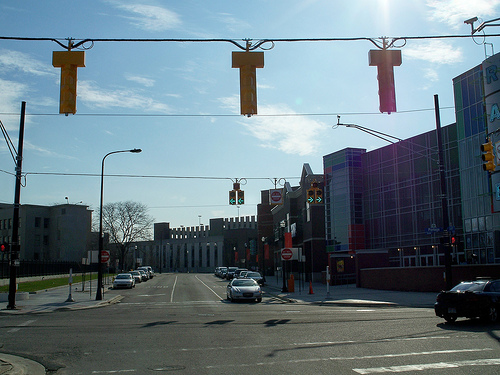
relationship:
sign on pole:
[280, 246, 303, 258] [277, 217, 296, 292]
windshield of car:
[455, 280, 485, 292] [435, 275, 499, 331]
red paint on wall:
[360, 270, 435, 292] [348, 257, 460, 293]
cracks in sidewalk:
[17, 346, 62, 372] [2, 354, 40, 374]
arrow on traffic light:
[227, 197, 239, 209] [209, 175, 259, 208]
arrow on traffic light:
[237, 196, 248, 207] [209, 175, 259, 208]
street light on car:
[231, 44, 264, 117] [223, 277, 270, 308]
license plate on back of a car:
[446, 306, 463, 317] [437, 274, 499, 335]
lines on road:
[169, 269, 179, 311] [121, 262, 240, 312]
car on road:
[112, 274, 134, 290] [121, 262, 240, 312]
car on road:
[130, 270, 142, 282] [121, 262, 240, 312]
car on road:
[133, 263, 148, 279] [121, 262, 240, 312]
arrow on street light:
[229, 198, 236, 205] [227, 179, 244, 206]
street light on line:
[365, 44, 407, 119] [0, 34, 498, 40]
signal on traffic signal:
[227, 197, 244, 204] [305, 178, 326, 205]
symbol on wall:
[334, 257, 348, 273] [327, 251, 355, 283]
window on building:
[38, 213, 48, 229] [5, 193, 95, 271]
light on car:
[477, 130, 496, 179] [428, 275, 498, 329]